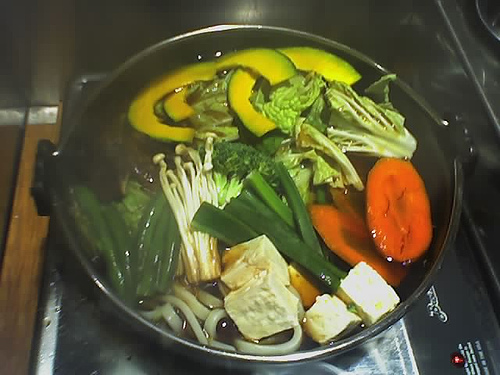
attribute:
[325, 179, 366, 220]
carrot — small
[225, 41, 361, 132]
avocado — juicy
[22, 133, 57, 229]
handle — black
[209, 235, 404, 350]
tofu — white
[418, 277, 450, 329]
brand — lack, white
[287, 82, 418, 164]
lettuce — crisp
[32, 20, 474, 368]
pot — metal, black